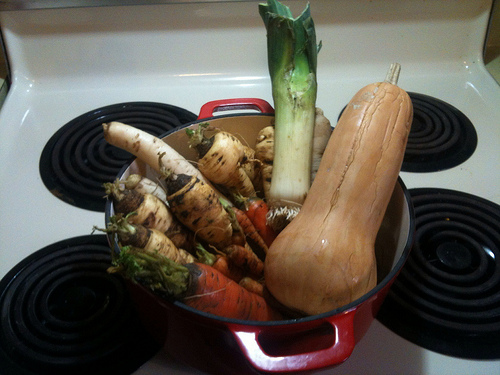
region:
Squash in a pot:
[261, 58, 421, 322]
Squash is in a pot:
[260, 58, 417, 323]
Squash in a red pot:
[260, 59, 420, 323]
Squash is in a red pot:
[266, 55, 421, 315]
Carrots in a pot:
[113, 193, 296, 326]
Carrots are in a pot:
[110, 185, 298, 328]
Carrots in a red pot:
[100, 188, 296, 325]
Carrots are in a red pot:
[113, 187, 292, 329]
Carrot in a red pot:
[118, 243, 286, 328]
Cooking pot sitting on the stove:
[106, 97, 416, 373]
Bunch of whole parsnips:
[96, 103, 333, 262]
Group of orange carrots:
[105, 190, 285, 321]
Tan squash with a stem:
[260, 63, 415, 310]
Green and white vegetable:
[256, 2, 326, 226]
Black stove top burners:
[0, 93, 498, 373]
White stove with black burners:
[2, 0, 498, 372]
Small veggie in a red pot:
[256, 1, 313, 193]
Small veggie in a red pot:
[318, 33, 376, 282]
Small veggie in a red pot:
[170, 271, 281, 323]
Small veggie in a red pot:
[174, 251, 279, 280]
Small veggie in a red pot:
[181, 186, 273, 276]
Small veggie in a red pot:
[195, 138, 260, 207]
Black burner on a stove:
[403, 182, 493, 344]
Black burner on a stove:
[396, 78, 483, 180]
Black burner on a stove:
[39, 88, 177, 198]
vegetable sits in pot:
[265, 58, 417, 319]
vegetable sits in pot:
[257, 0, 319, 222]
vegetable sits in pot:
[182, 115, 268, 198]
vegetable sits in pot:
[97, 118, 199, 185]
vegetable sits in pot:
[159, 168, 262, 271]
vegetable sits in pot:
[103, 179, 185, 242]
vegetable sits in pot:
[119, 246, 270, 324]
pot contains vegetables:
[101, 95, 413, 373]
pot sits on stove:
[106, 95, 416, 372]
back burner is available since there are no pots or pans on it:
[36, 95, 199, 213]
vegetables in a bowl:
[104, 50, 405, 322]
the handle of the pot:
[213, 305, 379, 363]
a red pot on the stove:
[110, 109, 427, 349]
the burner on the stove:
[396, 189, 496, 366]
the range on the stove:
[7, 62, 471, 369]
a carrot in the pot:
[181, 269, 273, 318]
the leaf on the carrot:
[123, 252, 194, 293]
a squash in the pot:
[292, 68, 407, 294]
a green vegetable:
[268, 62, 308, 194]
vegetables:
[120, 129, 385, 313]